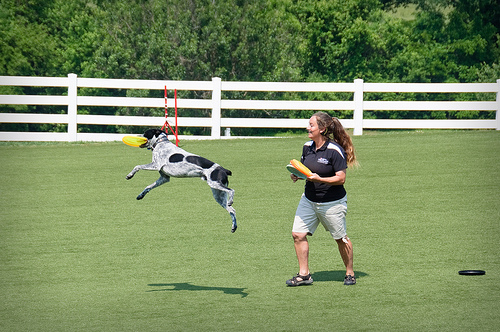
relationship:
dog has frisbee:
[122, 127, 246, 236] [120, 132, 149, 148]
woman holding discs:
[276, 107, 372, 290] [282, 156, 318, 184]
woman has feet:
[276, 107, 372, 290] [283, 267, 365, 290]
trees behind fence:
[1, 1, 500, 137] [0, 67, 500, 138]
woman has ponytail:
[276, 107, 372, 290] [312, 112, 359, 165]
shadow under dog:
[142, 276, 256, 309] [122, 127, 246, 236]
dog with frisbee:
[122, 127, 246, 236] [120, 132, 149, 148]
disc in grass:
[454, 267, 489, 278] [1, 140, 499, 330]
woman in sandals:
[276, 107, 372, 290] [282, 270, 360, 289]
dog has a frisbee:
[122, 127, 246, 236] [120, 132, 149, 148]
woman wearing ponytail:
[276, 107, 372, 290] [312, 112, 359, 165]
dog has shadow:
[122, 127, 246, 236] [142, 276, 256, 309]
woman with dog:
[276, 107, 372, 290] [122, 127, 246, 236]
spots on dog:
[169, 149, 234, 185] [122, 127, 246, 236]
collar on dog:
[149, 136, 170, 150] [122, 127, 246, 236]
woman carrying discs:
[276, 107, 372, 290] [282, 156, 318, 184]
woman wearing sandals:
[276, 107, 372, 290] [282, 270, 360, 289]